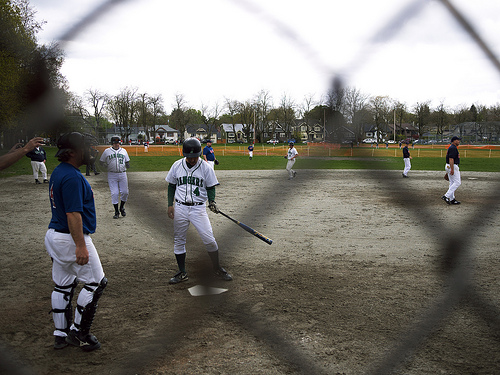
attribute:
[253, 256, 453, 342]
ground — moist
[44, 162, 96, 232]
jersey — blue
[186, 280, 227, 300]
home plate — white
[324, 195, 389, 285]
dirt — brown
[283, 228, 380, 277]
dirt — brown, sandy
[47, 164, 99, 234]
shirt — blue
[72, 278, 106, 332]
guard — black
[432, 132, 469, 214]
pitcher — for baseball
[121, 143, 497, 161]
fence — metal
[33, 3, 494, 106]
sky — partially cloudy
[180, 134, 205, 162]
helmet — black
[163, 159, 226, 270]
uniform — blue, white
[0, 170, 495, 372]
ground — dirt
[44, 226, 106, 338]
pants — white, baggy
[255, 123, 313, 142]
houses — two story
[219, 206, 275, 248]
bat — black, beige, blue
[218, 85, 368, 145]
trees — tall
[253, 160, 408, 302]
field — baseball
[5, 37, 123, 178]
tree — large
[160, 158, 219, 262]
uniform — white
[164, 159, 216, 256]
jersey — white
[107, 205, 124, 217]
base — third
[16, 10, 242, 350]
fence — chain link